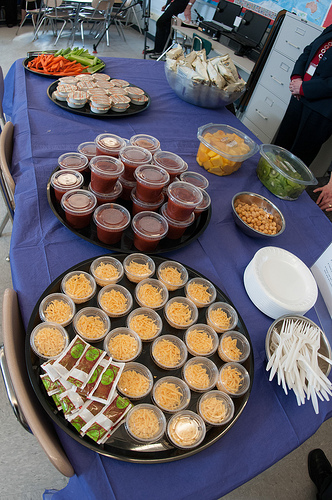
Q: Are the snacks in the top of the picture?
A: Yes, the snacks are in the top of the image.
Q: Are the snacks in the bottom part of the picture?
A: No, the snacks are in the top of the image.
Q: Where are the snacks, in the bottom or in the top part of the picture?
A: The snacks are in the top of the image.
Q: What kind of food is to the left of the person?
A: The food is snacks.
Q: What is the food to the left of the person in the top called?
A: The food is snacks.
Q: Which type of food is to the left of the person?
A: The food is snacks.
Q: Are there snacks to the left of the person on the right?
A: Yes, there are snacks to the left of the person.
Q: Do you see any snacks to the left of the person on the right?
A: Yes, there are snacks to the left of the person.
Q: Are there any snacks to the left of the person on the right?
A: Yes, there are snacks to the left of the person.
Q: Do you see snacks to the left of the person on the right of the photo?
A: Yes, there are snacks to the left of the person.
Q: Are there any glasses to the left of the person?
A: No, there are snacks to the left of the person.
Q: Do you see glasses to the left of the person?
A: No, there are snacks to the left of the person.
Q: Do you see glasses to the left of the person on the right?
A: No, there are snacks to the left of the person.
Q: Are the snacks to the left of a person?
A: Yes, the snacks are to the left of a person.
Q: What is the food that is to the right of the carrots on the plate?
A: The food is snacks.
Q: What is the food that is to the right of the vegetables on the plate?
A: The food is snacks.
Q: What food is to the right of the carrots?
A: The food is snacks.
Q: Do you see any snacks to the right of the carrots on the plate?
A: Yes, there are snacks to the right of the carrots.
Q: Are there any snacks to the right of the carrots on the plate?
A: Yes, there are snacks to the right of the carrots.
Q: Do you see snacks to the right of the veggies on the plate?
A: Yes, there are snacks to the right of the carrots.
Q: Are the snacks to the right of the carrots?
A: Yes, the snacks are to the right of the carrots.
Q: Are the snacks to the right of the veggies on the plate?
A: Yes, the snacks are to the right of the carrots.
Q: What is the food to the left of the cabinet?
A: The food is snacks.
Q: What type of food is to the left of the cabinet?
A: The food is snacks.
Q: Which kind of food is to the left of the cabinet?
A: The food is snacks.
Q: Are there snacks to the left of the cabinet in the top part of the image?
A: Yes, there are snacks to the left of the cabinet.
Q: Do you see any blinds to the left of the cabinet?
A: No, there are snacks to the left of the cabinet.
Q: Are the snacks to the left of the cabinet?
A: Yes, the snacks are to the left of the cabinet.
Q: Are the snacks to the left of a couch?
A: No, the snacks are to the left of the cabinet.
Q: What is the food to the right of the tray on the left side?
A: The food is snacks.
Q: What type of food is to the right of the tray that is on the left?
A: The food is snacks.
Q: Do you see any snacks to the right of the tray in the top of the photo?
A: Yes, there are snacks to the right of the tray.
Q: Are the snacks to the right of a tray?
A: Yes, the snacks are to the right of a tray.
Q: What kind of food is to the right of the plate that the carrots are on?
A: The food is snacks.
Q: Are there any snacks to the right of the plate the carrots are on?
A: Yes, there are snacks to the right of the plate.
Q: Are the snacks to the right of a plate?
A: Yes, the snacks are to the right of a plate.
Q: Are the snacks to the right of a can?
A: No, the snacks are to the right of a plate.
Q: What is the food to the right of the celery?
A: The food is snacks.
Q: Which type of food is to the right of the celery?
A: The food is snacks.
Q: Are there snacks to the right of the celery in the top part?
A: Yes, there are snacks to the right of the celery.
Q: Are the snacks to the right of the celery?
A: Yes, the snacks are to the right of the celery.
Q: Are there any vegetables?
A: Yes, there are vegetables.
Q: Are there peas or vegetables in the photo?
A: Yes, there are vegetables.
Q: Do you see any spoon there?
A: No, there are no spoons.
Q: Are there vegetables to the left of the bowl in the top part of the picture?
A: Yes, there are vegetables to the left of the bowl.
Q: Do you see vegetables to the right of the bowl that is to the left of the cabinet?
A: No, the vegetables are to the left of the bowl.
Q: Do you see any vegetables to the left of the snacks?
A: Yes, there are vegetables to the left of the snacks.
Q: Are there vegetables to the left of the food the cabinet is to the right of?
A: Yes, there are vegetables to the left of the snacks.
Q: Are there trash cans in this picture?
A: No, there are no trash cans.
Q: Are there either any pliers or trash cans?
A: No, there are no trash cans or pliers.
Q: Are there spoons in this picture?
A: No, there are no spoons.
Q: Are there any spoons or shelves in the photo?
A: No, there are no spoons or shelves.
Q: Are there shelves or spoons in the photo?
A: No, there are no spoons or shelves.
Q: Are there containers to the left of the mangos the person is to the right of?
A: Yes, there is a container to the left of the mangoes.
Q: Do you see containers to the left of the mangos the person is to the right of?
A: Yes, there is a container to the left of the mangoes.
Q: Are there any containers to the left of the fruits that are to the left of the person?
A: Yes, there is a container to the left of the mangoes.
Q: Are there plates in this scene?
A: Yes, there is a plate.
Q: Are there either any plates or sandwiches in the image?
A: Yes, there is a plate.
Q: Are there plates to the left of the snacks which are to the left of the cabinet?
A: Yes, there is a plate to the left of the snacks.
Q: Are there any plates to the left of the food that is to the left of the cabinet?
A: Yes, there is a plate to the left of the snacks.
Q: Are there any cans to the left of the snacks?
A: No, there is a plate to the left of the snacks.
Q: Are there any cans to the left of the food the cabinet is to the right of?
A: No, there is a plate to the left of the snacks.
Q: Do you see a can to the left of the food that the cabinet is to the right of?
A: No, there is a plate to the left of the snacks.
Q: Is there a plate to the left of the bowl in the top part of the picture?
A: Yes, there is a plate to the left of the bowl.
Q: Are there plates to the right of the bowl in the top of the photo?
A: No, the plate is to the left of the bowl.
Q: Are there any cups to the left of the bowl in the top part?
A: No, there is a plate to the left of the bowl.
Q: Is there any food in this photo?
A: Yes, there is food.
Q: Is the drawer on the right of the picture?
A: Yes, the drawer is on the right of the image.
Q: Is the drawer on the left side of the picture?
A: No, the drawer is on the right of the image.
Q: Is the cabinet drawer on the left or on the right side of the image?
A: The drawer is on the right of the image.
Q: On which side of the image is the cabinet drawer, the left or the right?
A: The drawer is on the right of the image.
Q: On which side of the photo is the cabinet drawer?
A: The drawer is on the right of the image.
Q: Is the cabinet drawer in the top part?
A: Yes, the drawer is in the top of the image.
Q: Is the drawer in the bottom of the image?
A: No, the drawer is in the top of the image.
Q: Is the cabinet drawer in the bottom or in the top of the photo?
A: The drawer is in the top of the image.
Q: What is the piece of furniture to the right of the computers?
A: The piece of furniture is a drawer.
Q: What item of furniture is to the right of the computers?
A: The piece of furniture is a drawer.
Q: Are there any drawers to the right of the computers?
A: Yes, there is a drawer to the right of the computers.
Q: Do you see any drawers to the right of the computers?
A: Yes, there is a drawer to the right of the computers.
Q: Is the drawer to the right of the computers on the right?
A: Yes, the drawer is to the right of the computers.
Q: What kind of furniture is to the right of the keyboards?
A: The piece of furniture is a drawer.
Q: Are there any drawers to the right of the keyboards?
A: Yes, there is a drawer to the right of the keyboards.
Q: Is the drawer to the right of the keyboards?
A: Yes, the drawer is to the right of the keyboards.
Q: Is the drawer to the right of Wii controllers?
A: No, the drawer is to the right of the keyboards.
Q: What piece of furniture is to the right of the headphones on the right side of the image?
A: The piece of furniture is a drawer.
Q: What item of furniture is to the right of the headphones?
A: The piece of furniture is a drawer.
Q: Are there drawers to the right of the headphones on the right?
A: Yes, there is a drawer to the right of the headphones.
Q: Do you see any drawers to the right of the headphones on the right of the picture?
A: Yes, there is a drawer to the right of the headphones.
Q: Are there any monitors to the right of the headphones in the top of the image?
A: No, there is a drawer to the right of the headphones.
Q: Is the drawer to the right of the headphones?
A: Yes, the drawer is to the right of the headphones.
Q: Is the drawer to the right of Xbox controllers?
A: No, the drawer is to the right of the headphones.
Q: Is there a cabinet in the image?
A: Yes, there is a cabinet.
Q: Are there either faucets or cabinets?
A: Yes, there is a cabinet.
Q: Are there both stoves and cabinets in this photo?
A: No, there is a cabinet but no stoves.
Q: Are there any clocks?
A: No, there are no clocks.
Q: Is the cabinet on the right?
A: Yes, the cabinet is on the right of the image.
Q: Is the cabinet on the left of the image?
A: No, the cabinet is on the right of the image.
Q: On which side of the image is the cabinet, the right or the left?
A: The cabinet is on the right of the image.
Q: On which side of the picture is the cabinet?
A: The cabinet is on the right of the image.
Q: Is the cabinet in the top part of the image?
A: Yes, the cabinet is in the top of the image.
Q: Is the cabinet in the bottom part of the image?
A: No, the cabinet is in the top of the image.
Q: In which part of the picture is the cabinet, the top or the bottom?
A: The cabinet is in the top of the image.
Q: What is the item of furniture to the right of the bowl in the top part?
A: The piece of furniture is a cabinet.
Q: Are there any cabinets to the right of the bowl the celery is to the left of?
A: Yes, there is a cabinet to the right of the bowl.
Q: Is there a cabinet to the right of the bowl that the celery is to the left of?
A: Yes, there is a cabinet to the right of the bowl.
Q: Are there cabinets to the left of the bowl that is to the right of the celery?
A: No, the cabinet is to the right of the bowl.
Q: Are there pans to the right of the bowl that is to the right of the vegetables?
A: No, there is a cabinet to the right of the bowl.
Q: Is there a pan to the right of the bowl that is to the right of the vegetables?
A: No, there is a cabinet to the right of the bowl.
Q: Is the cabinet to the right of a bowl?
A: Yes, the cabinet is to the right of a bowl.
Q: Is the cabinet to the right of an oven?
A: No, the cabinet is to the right of a bowl.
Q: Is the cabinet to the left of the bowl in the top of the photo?
A: No, the cabinet is to the right of the bowl.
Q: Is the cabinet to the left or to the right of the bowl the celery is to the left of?
A: The cabinet is to the right of the bowl.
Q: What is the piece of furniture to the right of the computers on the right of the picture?
A: The piece of furniture is a cabinet.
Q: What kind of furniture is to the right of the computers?
A: The piece of furniture is a cabinet.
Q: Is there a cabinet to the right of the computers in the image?
A: Yes, there is a cabinet to the right of the computers.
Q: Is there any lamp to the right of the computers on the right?
A: No, there is a cabinet to the right of the computers.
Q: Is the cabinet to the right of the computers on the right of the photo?
A: Yes, the cabinet is to the right of the computers.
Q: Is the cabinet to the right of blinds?
A: No, the cabinet is to the right of the computers.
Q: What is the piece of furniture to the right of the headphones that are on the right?
A: The piece of furniture is a cabinet.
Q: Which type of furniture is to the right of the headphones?
A: The piece of furniture is a cabinet.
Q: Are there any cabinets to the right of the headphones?
A: Yes, there is a cabinet to the right of the headphones.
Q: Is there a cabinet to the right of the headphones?
A: Yes, there is a cabinet to the right of the headphones.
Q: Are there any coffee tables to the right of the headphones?
A: No, there is a cabinet to the right of the headphones.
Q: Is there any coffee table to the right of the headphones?
A: No, there is a cabinet to the right of the headphones.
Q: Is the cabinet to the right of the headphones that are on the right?
A: Yes, the cabinet is to the right of the headphones.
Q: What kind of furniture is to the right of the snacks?
A: The piece of furniture is a cabinet.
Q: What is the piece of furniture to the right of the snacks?
A: The piece of furniture is a cabinet.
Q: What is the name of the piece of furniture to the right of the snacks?
A: The piece of furniture is a cabinet.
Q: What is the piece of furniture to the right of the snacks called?
A: The piece of furniture is a cabinet.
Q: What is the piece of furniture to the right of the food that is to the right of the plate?
A: The piece of furniture is a cabinet.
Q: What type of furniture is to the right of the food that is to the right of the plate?
A: The piece of furniture is a cabinet.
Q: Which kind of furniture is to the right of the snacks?
A: The piece of furniture is a cabinet.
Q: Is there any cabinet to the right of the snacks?
A: Yes, there is a cabinet to the right of the snacks.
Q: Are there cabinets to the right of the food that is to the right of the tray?
A: Yes, there is a cabinet to the right of the snacks.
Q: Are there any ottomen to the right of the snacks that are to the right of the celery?
A: No, there is a cabinet to the right of the snacks.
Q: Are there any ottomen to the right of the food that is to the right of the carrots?
A: No, there is a cabinet to the right of the snacks.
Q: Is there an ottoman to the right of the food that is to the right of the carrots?
A: No, there is a cabinet to the right of the snacks.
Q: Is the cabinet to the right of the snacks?
A: Yes, the cabinet is to the right of the snacks.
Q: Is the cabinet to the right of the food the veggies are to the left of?
A: Yes, the cabinet is to the right of the snacks.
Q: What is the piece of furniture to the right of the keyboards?
A: The piece of furniture is a cabinet.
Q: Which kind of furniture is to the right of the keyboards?
A: The piece of furniture is a cabinet.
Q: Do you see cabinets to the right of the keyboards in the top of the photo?
A: Yes, there is a cabinet to the right of the keyboards.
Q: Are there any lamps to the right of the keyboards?
A: No, there is a cabinet to the right of the keyboards.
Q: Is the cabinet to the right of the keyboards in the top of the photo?
A: Yes, the cabinet is to the right of the keyboards.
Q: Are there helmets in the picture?
A: No, there are no helmets.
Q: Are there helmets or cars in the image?
A: No, there are no helmets or cars.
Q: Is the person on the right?
A: Yes, the person is on the right of the image.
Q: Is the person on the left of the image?
A: No, the person is on the right of the image.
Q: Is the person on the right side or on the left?
A: The person is on the right of the image.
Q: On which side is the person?
A: The person is on the right of the image.